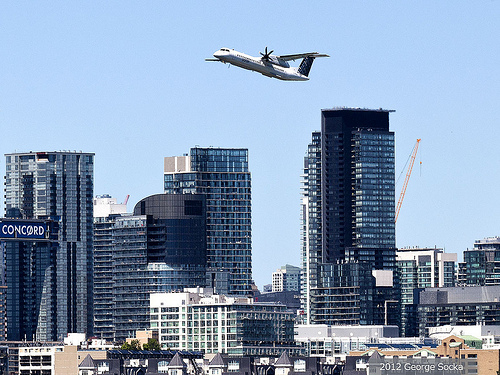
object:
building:
[398, 247, 460, 331]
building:
[453, 237, 499, 286]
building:
[146, 186, 213, 265]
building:
[85, 207, 148, 344]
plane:
[205, 48, 330, 81]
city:
[0, 128, 499, 374]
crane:
[395, 139, 423, 222]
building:
[350, 127, 408, 237]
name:
[1, 225, 44, 236]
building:
[0, 156, 91, 335]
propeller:
[259, 46, 274, 60]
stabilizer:
[277, 52, 330, 77]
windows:
[236, 54, 284, 72]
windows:
[354, 131, 395, 250]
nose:
[212, 52, 226, 56]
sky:
[37, 14, 161, 79]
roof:
[460, 335, 481, 341]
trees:
[116, 337, 162, 350]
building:
[113, 346, 191, 374]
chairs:
[198, 288, 253, 304]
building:
[150, 290, 300, 351]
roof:
[420, 286, 499, 304]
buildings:
[198, 148, 254, 283]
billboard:
[0, 225, 44, 235]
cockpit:
[219, 48, 230, 52]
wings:
[260, 51, 330, 76]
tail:
[297, 56, 315, 77]